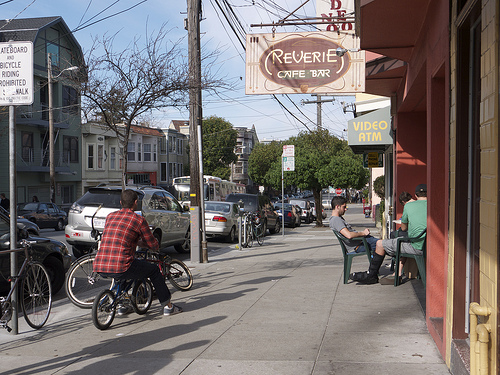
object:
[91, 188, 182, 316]
boy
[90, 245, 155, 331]
bicycle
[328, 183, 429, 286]
guys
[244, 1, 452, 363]
cafe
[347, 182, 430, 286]
man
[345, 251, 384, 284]
cast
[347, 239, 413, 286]
leg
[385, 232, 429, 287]
chair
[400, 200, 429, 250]
shirt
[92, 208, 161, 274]
shirt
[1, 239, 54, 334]
bicycle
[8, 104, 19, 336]
pole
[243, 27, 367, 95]
sign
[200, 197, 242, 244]
car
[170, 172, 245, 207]
bus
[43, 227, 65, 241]
road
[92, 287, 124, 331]
wheel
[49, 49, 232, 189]
tree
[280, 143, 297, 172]
signs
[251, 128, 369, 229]
tree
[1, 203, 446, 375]
sidewalk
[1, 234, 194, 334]
bicycles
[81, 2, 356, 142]
sky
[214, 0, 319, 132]
wires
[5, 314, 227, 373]
shadow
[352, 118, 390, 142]
words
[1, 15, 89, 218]
building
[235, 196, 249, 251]
parking meter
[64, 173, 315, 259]
cars